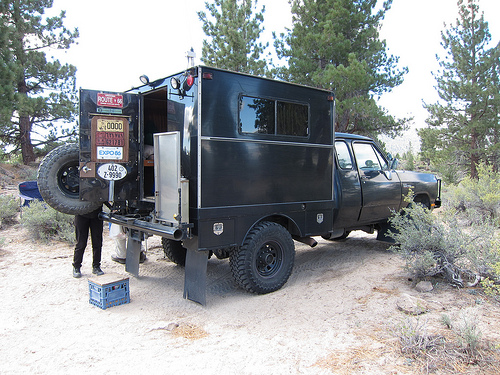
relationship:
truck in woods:
[78, 65, 441, 296] [3, 1, 498, 374]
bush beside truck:
[388, 184, 497, 286] [78, 65, 441, 296]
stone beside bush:
[392, 290, 430, 316] [388, 184, 497, 286]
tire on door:
[35, 142, 100, 216] [78, 86, 143, 204]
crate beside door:
[87, 270, 134, 310] [78, 86, 143, 204]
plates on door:
[95, 93, 127, 182] [78, 86, 143, 204]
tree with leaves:
[417, 2, 500, 172] [429, 69, 441, 77]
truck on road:
[78, 65, 441, 296] [1, 220, 461, 374]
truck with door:
[78, 65, 441, 296] [78, 86, 143, 204]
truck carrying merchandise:
[78, 65, 441, 296] [143, 144, 155, 160]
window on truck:
[351, 139, 384, 170] [78, 65, 441, 296]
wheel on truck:
[232, 218, 297, 295] [78, 65, 441, 296]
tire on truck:
[35, 142, 100, 216] [78, 65, 441, 296]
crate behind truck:
[87, 270, 134, 310] [78, 65, 441, 296]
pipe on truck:
[97, 210, 181, 241] [78, 65, 441, 296]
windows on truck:
[238, 93, 312, 138] [78, 65, 441, 296]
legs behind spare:
[70, 214, 105, 279] [35, 142, 100, 216]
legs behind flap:
[70, 214, 105, 279] [122, 229, 141, 277]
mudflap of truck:
[122, 229, 141, 277] [78, 65, 441, 296]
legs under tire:
[70, 214, 105, 279] [35, 142, 100, 216]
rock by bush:
[412, 278, 435, 294] [388, 184, 497, 286]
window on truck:
[235, 92, 277, 134] [78, 65, 441, 296]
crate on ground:
[87, 270, 134, 310] [83, 301, 140, 316]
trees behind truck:
[197, 0, 406, 134] [78, 65, 441, 296]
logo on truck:
[97, 164, 132, 180] [78, 65, 441, 296]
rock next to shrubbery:
[412, 278, 435, 294] [388, 184, 497, 286]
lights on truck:
[166, 72, 198, 97] [78, 65, 441, 296]